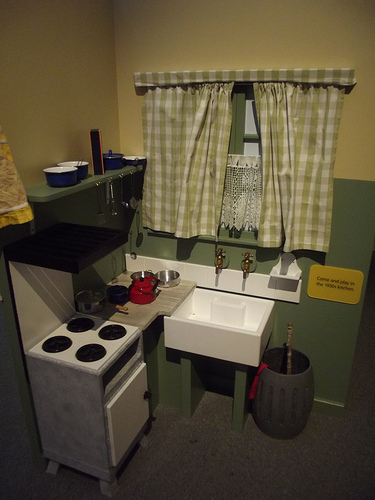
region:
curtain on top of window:
[133, 72, 356, 233]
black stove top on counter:
[49, 314, 128, 370]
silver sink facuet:
[197, 251, 263, 274]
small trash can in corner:
[251, 345, 307, 438]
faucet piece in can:
[284, 321, 299, 357]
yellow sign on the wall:
[310, 265, 361, 306]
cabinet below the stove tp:
[99, 369, 150, 464]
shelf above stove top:
[1, 153, 155, 221]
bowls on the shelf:
[43, 152, 88, 211]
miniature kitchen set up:
[0, 40, 374, 475]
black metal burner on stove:
[42, 334, 69, 352]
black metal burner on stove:
[80, 344, 108, 362]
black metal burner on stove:
[100, 324, 127, 343]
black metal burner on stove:
[62, 314, 93, 335]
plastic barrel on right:
[255, 342, 319, 445]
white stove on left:
[30, 314, 137, 460]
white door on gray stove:
[92, 387, 154, 445]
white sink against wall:
[179, 266, 262, 354]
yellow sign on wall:
[307, 259, 369, 300]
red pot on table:
[123, 261, 157, 304]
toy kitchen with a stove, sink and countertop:
[23, 189, 301, 432]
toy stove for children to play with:
[2, 245, 148, 428]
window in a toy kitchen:
[134, 73, 328, 253]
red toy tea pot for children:
[132, 278, 155, 301]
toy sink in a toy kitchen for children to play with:
[194, 286, 245, 427]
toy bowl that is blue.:
[43, 169, 76, 186]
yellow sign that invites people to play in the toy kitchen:
[311, 264, 357, 305]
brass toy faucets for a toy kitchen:
[216, 248, 246, 279]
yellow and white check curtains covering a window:
[133, 73, 219, 239]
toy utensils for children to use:
[94, 183, 135, 209]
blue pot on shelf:
[44, 167, 81, 188]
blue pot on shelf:
[59, 161, 88, 178]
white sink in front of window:
[166, 286, 275, 366]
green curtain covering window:
[128, 69, 357, 253]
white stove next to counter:
[8, 255, 154, 497]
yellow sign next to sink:
[307, 266, 364, 304]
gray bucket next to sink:
[250, 347, 312, 436]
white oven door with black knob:
[106, 359, 151, 469]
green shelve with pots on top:
[17, 164, 148, 202]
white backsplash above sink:
[125, 254, 300, 301]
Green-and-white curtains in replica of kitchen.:
[133, 68, 358, 253]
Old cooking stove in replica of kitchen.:
[2, 220, 153, 495]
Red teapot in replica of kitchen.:
[127, 272, 160, 304]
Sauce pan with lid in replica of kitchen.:
[75, 287, 128, 314]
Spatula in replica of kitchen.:
[95, 180, 106, 226]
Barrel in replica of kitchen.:
[252, 346, 314, 438]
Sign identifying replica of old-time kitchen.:
[306, 264, 364, 304]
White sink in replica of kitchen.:
[163, 286, 276, 367]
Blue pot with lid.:
[102, 149, 123, 170]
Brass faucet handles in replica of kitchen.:
[213, 246, 254, 279]